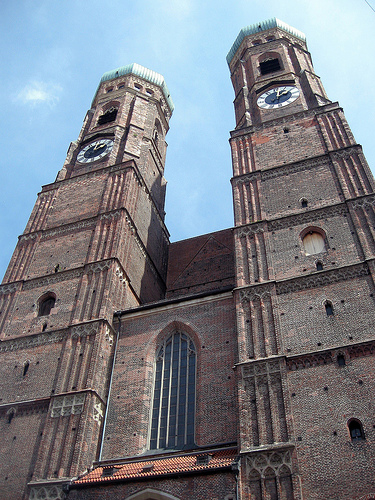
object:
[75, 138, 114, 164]
clock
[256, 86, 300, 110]
clock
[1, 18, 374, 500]
building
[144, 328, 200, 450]
window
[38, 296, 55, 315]
window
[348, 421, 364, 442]
window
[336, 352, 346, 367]
window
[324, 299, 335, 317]
window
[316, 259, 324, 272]
window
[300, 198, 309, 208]
window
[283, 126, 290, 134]
window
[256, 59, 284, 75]
window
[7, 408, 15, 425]
window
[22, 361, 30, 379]
window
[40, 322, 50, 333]
window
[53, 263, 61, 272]
window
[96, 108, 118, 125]
window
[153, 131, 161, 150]
window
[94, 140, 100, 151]
hand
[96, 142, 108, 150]
hand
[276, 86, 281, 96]
hand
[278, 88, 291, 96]
hand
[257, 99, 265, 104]
roman numeral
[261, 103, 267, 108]
roman numeral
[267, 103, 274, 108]
roman numeral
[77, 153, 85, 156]
roman numeral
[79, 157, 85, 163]
roman numeral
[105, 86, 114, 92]
window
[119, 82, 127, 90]
window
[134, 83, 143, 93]
window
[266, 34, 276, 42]
window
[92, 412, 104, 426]
hole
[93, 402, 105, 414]
hole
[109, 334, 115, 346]
hole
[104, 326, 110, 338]
hole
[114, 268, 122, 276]
hole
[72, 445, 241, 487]
tile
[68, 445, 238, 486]
roof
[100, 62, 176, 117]
parapet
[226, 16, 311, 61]
parapet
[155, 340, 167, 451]
mullion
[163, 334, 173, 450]
mullion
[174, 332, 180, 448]
mullion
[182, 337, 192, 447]
mullion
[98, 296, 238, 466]
wall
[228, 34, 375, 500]
wall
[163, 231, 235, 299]
wall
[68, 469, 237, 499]
wall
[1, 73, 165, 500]
wall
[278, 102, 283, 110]
roman numeral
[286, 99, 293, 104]
roman numeral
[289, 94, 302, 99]
roman numeral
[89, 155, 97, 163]
roman numeral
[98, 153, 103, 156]
roman numeral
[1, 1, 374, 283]
sky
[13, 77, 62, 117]
cloud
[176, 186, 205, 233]
cloud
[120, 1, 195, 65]
cloud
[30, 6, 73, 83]
cloud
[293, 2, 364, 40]
cloud